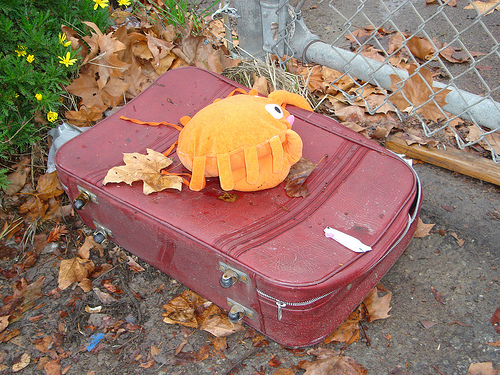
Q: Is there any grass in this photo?
A: Yes, there is grass.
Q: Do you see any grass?
A: Yes, there is grass.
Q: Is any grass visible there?
A: Yes, there is grass.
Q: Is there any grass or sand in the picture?
A: Yes, there is grass.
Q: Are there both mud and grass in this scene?
A: No, there is grass but no mud.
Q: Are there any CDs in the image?
A: No, there are no cds.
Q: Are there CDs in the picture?
A: No, there are no cds.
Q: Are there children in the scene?
A: No, there are no children.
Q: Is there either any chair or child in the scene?
A: No, there are no children or chairs.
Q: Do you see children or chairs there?
A: No, there are no children or chairs.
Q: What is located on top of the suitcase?
A: The stuffed animal is on top of the suitcase.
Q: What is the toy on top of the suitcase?
A: The toy is a stuffed animal.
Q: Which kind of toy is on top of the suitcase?
A: The toy is a stuffed animal.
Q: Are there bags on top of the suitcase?
A: No, there is a stuffed animal on top of the suitcase.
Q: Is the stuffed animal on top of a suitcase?
A: Yes, the stuffed animal is on top of a suitcase.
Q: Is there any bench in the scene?
A: No, there are no benches.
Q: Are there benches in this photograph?
A: No, there are no benches.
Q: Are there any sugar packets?
A: No, there are no sugar packets.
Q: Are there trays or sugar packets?
A: No, there are no sugar packets or trays.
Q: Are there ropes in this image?
A: No, there are no ropes.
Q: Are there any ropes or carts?
A: No, there are no ropes or carts.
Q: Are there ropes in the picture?
A: No, there are no ropes.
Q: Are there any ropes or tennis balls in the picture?
A: No, there are no ropes or tennis balls.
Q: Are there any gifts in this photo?
A: No, there are no gifts.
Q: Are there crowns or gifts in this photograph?
A: No, there are no gifts or crowns.